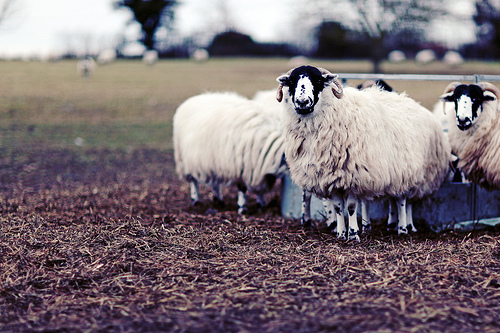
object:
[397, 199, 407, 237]
leg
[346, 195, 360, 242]
leg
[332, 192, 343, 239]
leg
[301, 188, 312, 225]
leg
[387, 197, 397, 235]
leg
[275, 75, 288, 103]
ear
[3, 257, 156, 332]
straw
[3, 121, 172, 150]
grass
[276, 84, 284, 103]
horn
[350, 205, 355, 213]
black spot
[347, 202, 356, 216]
knee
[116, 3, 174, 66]
tall tree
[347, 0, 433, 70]
tall tree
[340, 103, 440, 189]
white wool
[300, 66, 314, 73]
black wool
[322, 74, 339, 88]
left ear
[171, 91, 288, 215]
sheep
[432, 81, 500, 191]
sheep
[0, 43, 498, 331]
yard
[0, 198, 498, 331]
twig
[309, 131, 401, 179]
long fur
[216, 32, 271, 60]
building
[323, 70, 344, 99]
horn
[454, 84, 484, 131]
face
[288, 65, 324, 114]
face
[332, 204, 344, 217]
spots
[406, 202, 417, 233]
legs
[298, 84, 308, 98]
spots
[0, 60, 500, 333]
field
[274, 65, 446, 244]
sheep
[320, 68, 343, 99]
ears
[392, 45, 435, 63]
bundles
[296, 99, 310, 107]
nose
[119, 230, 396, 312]
ground